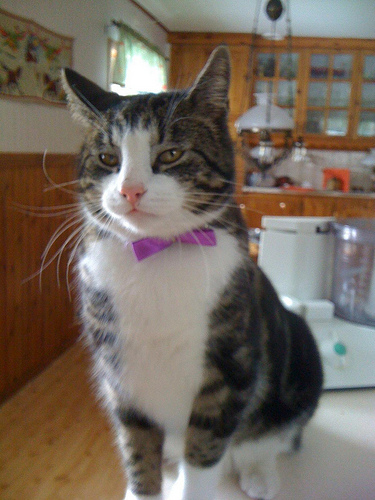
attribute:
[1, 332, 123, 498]
floors — yellow, hardwood, pine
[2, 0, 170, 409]
wall — white, wood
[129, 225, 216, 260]
bow tie — Purple 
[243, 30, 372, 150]
cabinets — upper cabinets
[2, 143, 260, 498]
table —   for kitchen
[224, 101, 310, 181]
fixture — a light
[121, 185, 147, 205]
nose — pink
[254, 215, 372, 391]
blender — large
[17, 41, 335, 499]
cat —  gray and white,  eye , striped 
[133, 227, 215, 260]
bow tie — purple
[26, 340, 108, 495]
floor — Brown 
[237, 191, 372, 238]
kitchen cabinets — brown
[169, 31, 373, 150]
kitchen cabinets — brown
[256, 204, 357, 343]
processor — white, food processor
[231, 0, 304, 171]
light fixture —  kitchen's,  hanging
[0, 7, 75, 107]
picture — framed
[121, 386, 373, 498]
counter — kitchen counter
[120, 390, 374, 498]
table — white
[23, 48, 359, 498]
tabby — brown, black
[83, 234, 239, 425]
chest — white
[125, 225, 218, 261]
ribbon — purple